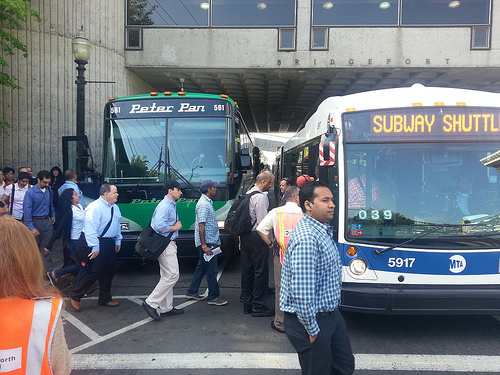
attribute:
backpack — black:
[224, 182, 264, 239]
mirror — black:
[315, 123, 346, 165]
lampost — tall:
[53, 24, 112, 254]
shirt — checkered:
[275, 164, 366, 331]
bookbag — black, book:
[217, 184, 268, 239]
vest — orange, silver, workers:
[4, 284, 74, 369]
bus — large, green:
[104, 100, 251, 242]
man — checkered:
[279, 180, 354, 373]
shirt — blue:
[277, 212, 342, 335]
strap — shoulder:
[96, 204, 116, 240]